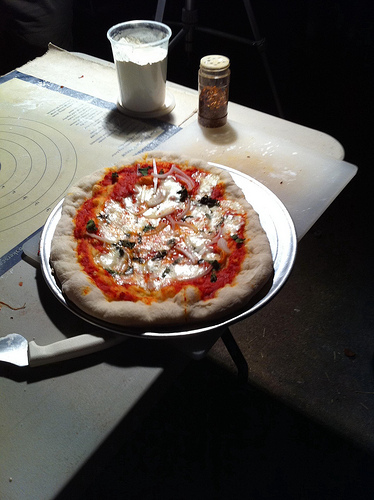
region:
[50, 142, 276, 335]
this looks like a homemade pizza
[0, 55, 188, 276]
the dough board helps the cook to shape her dough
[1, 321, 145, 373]
a cutter for the dough or the pizza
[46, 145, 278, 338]
the lily-white dough seems to indicate the pizza is still uncooked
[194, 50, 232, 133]
a little bottle of seasoning on the table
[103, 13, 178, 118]
flour used to keep the dough from sticking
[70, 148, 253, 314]
the red stuff might be tomato sauce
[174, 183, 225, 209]
sliced olives are on the pizza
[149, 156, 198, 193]
sliced onions are a part of this pizza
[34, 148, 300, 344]
the uncooked pizza is on a metal baking pan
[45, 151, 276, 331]
Pizza sits on pan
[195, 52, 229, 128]
Chili pepper flakes are in a shaker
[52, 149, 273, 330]
Red sauce is on pizza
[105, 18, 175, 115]
Flour is in a plastic cup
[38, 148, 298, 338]
Metal tray is on the table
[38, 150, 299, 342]
Metal tray is under pizza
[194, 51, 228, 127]
Jar of chili pepper flakes is on table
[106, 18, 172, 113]
Plastic cup full of flour is on the table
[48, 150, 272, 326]
Cheese is on pizza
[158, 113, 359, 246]
Cutting board is on the table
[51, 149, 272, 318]
an uncooked single serve pizza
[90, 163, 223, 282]
white parmasean cheese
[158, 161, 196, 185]
a piece of red onion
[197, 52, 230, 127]
a container of crushed red pepper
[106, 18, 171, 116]
plastic container of cheese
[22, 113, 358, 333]
a frosted plastic cutting board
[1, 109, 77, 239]
a chart used to size pizza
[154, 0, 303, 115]
bottom of a ladder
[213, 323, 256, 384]
leg of a folding banquet table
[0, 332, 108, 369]
white handle of a knife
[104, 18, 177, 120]
A cup of flour on the table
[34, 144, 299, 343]
A pizza on a tray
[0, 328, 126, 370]
Pizza cutter partly under the tray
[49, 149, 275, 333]
Pizza with sauce, cheese and onion.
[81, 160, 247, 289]
Green spices on the pizza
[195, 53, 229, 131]
A jar of seasoning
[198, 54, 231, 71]
Wholes on top of the jar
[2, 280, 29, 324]
A mess on the table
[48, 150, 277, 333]
The crust is doughy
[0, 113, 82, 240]
Concentric circles on the paper